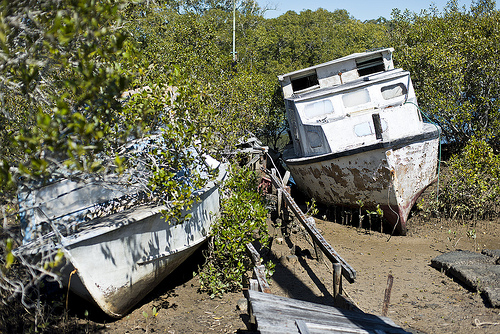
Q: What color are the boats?
A: White.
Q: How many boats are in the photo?
A: 2.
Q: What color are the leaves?
A: Green.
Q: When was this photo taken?
A: During the day.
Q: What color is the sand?
A: Brown.